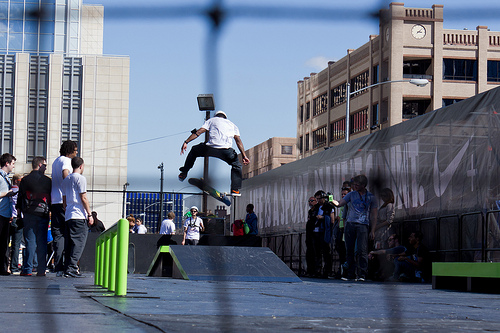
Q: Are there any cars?
A: No, there are no cars.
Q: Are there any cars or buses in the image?
A: No, there are no cars or buses.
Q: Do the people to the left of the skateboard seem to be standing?
A: Yes, the people are standing.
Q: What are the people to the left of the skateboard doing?
A: The people are standing.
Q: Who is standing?
A: The people are standing.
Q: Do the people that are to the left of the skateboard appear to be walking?
A: No, the people are standing.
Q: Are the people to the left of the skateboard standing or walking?
A: The people are standing.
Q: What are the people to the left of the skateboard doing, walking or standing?
A: The people are standing.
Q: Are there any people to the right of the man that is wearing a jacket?
A: Yes, there are people to the right of the man.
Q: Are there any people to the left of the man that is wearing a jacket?
A: No, the people are to the right of the man.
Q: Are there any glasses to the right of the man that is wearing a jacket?
A: No, there are people to the right of the man.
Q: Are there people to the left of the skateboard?
A: Yes, there are people to the left of the skateboard.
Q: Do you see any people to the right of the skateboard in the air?
A: No, the people are to the left of the skateboard.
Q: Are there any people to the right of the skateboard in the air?
A: No, the people are to the left of the skateboard.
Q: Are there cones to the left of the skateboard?
A: No, there are people to the left of the skateboard.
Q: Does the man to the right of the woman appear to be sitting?
A: Yes, the man is sitting.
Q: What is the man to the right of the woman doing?
A: The man is sitting.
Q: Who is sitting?
A: The man is sitting.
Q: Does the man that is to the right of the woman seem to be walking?
A: No, the man is sitting.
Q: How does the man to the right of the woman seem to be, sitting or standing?
A: The man is sitting.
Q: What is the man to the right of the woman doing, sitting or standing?
A: The man is sitting.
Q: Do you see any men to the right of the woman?
A: Yes, there is a man to the right of the woman.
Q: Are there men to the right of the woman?
A: Yes, there is a man to the right of the woman.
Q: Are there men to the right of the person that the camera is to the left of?
A: Yes, there is a man to the right of the woman.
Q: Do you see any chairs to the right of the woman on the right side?
A: No, there is a man to the right of the woman.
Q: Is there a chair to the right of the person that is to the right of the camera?
A: No, there is a man to the right of the woman.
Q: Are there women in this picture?
A: Yes, there is a woman.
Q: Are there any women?
A: Yes, there is a woman.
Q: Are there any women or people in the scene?
A: Yes, there is a woman.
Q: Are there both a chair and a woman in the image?
A: No, there is a woman but no chairs.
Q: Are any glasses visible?
A: No, there are no glasses.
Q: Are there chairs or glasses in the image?
A: No, there are no glasses or chairs.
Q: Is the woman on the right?
A: Yes, the woman is on the right of the image.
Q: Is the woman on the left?
A: No, the woman is on the right of the image.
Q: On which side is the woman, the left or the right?
A: The woman is on the right of the image.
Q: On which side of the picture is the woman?
A: The woman is on the right of the image.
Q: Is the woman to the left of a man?
A: No, the woman is to the right of a man.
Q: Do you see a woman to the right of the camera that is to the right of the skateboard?
A: Yes, there is a woman to the right of the camera.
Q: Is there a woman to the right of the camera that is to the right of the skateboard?
A: Yes, there is a woman to the right of the camera.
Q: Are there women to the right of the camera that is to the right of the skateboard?
A: Yes, there is a woman to the right of the camera.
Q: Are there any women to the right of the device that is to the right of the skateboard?
A: Yes, there is a woman to the right of the camera.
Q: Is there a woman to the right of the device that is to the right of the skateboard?
A: Yes, there is a woman to the right of the camera.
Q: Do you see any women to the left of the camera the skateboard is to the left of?
A: No, the woman is to the right of the camera.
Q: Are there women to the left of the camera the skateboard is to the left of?
A: No, the woman is to the right of the camera.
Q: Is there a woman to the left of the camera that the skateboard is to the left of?
A: No, the woman is to the right of the camera.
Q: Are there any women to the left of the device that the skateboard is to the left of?
A: No, the woman is to the right of the camera.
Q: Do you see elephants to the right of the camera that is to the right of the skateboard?
A: No, there is a woman to the right of the camera.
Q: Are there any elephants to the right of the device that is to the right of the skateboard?
A: No, there is a woman to the right of the camera.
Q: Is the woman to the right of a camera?
A: Yes, the woman is to the right of a camera.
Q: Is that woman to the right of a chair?
A: No, the woman is to the right of a camera.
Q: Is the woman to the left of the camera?
A: No, the woman is to the right of the camera.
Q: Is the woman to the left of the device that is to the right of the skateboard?
A: No, the woman is to the right of the camera.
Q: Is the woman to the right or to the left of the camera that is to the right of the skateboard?
A: The woman is to the right of the camera.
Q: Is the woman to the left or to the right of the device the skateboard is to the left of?
A: The woman is to the right of the camera.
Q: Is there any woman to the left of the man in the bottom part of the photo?
A: Yes, there is a woman to the left of the man.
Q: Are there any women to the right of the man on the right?
A: No, the woman is to the left of the man.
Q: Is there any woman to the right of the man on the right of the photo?
A: No, the woman is to the left of the man.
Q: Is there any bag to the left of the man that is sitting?
A: No, there is a woman to the left of the man.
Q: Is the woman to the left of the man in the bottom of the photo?
A: Yes, the woman is to the left of the man.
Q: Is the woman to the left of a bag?
A: No, the woman is to the left of the man.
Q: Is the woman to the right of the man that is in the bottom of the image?
A: No, the woman is to the left of the man.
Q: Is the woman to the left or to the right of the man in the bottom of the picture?
A: The woman is to the left of the man.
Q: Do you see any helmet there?
A: No, there are no helmets.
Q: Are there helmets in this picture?
A: No, there are no helmets.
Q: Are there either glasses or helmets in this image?
A: No, there are no helmets or glasses.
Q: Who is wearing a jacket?
A: The man is wearing a jacket.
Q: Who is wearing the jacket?
A: The man is wearing a jacket.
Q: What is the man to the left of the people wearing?
A: The man is wearing a jacket.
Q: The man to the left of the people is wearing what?
A: The man is wearing a jacket.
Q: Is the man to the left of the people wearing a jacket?
A: Yes, the man is wearing a jacket.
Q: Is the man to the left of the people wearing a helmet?
A: No, the man is wearing a jacket.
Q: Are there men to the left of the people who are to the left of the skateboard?
A: Yes, there is a man to the left of the people.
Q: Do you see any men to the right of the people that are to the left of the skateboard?
A: No, the man is to the left of the people.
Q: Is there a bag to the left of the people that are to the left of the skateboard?
A: No, there is a man to the left of the people.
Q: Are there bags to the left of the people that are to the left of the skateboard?
A: No, there is a man to the left of the people.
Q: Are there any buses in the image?
A: No, there are no buses.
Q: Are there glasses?
A: No, there are no glasses.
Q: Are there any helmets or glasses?
A: No, there are no glasses or helmets.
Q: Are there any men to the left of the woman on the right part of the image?
A: Yes, there is a man to the left of the woman.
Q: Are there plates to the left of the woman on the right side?
A: No, there is a man to the left of the woman.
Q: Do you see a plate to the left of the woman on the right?
A: No, there is a man to the left of the woman.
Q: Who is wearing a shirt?
A: The man is wearing a shirt.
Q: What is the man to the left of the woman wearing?
A: The man is wearing a shirt.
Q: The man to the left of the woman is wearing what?
A: The man is wearing a shirt.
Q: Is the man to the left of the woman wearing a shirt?
A: Yes, the man is wearing a shirt.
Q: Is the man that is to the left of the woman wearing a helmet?
A: No, the man is wearing a shirt.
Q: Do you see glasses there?
A: No, there are no glasses.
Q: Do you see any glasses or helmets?
A: No, there are no glasses or helmets.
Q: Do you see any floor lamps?
A: No, there are no floor lamps.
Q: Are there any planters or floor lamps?
A: No, there are no floor lamps or planters.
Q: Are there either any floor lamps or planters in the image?
A: No, there are no floor lamps or planters.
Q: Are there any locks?
A: No, there are no locks.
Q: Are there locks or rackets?
A: No, there are no locks or rackets.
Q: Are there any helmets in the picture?
A: No, there are no helmets.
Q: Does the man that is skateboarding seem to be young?
A: Yes, the man is young.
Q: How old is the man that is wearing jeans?
A: The man is young.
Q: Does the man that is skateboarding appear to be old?
A: No, the man is young.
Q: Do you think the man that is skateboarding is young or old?
A: The man is young.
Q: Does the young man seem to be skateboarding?
A: Yes, the man is skateboarding.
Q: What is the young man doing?
A: The man is skateboarding.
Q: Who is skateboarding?
A: The man is skateboarding.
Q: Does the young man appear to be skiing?
A: No, the man is skateboarding.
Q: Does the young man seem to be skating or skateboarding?
A: The man is skateboarding.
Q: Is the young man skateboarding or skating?
A: The man is skateboarding.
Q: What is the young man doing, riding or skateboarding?
A: The man is skateboarding.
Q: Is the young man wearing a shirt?
A: Yes, the man is wearing a shirt.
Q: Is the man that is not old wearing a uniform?
A: No, the man is wearing a shirt.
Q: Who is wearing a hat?
A: The man is wearing a hat.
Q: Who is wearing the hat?
A: The man is wearing a hat.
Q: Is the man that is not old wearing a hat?
A: Yes, the man is wearing a hat.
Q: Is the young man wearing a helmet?
A: No, the man is wearing a hat.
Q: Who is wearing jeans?
A: The man is wearing jeans.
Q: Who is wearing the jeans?
A: The man is wearing jeans.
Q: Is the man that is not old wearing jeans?
A: Yes, the man is wearing jeans.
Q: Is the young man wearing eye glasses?
A: No, the man is wearing jeans.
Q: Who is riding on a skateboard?
A: The man is riding on a skateboard.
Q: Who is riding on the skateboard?
A: The man is riding on a skateboard.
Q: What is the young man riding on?
A: The man is riding on a skateboard.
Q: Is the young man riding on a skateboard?
A: Yes, the man is riding on a skateboard.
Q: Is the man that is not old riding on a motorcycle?
A: No, the man is riding on a skateboard.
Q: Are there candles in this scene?
A: No, there are no candles.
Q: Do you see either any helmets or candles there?
A: No, there are no candles or helmets.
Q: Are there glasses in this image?
A: No, there are no glasses.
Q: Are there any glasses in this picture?
A: No, there are no glasses.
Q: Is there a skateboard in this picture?
A: Yes, there is a skateboard.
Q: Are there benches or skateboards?
A: Yes, there is a skateboard.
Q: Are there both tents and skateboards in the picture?
A: No, there is a skateboard but no tents.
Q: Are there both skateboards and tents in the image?
A: No, there is a skateboard but no tents.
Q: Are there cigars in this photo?
A: No, there are no cigars.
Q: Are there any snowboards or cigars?
A: No, there are no cigars or snowboards.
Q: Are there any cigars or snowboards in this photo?
A: No, there are no cigars or snowboards.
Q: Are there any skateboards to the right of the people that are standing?
A: Yes, there is a skateboard to the right of the people.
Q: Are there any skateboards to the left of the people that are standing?
A: No, the skateboard is to the right of the people.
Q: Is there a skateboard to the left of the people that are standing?
A: No, the skateboard is to the right of the people.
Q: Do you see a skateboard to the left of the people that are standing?
A: No, the skateboard is to the right of the people.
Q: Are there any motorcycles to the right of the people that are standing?
A: No, there is a skateboard to the right of the people.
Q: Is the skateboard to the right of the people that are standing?
A: Yes, the skateboard is to the right of the people.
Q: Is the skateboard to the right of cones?
A: No, the skateboard is to the right of the people.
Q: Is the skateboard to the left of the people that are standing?
A: No, the skateboard is to the right of the people.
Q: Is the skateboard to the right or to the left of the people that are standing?
A: The skateboard is to the right of the people.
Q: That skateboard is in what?
A: The skateboard is in the air.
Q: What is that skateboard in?
A: The skateboard is in the air.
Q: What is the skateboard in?
A: The skateboard is in the air.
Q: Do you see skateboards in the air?
A: Yes, there is a skateboard in the air.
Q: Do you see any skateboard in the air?
A: Yes, there is a skateboard in the air.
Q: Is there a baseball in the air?
A: No, there is a skateboard in the air.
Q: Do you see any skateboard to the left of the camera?
A: Yes, there is a skateboard to the left of the camera.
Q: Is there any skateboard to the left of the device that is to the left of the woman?
A: Yes, there is a skateboard to the left of the camera.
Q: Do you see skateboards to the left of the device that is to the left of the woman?
A: Yes, there is a skateboard to the left of the camera.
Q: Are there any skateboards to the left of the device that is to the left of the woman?
A: Yes, there is a skateboard to the left of the camera.